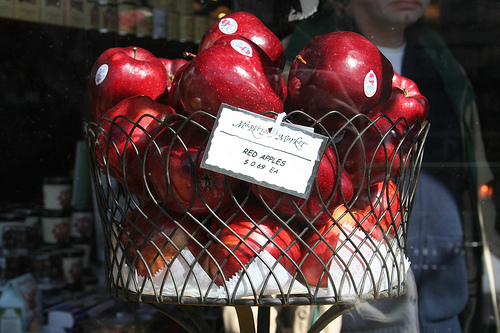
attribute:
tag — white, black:
[199, 101, 329, 201]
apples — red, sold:
[90, 11, 427, 286]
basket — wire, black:
[80, 112, 430, 306]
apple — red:
[285, 29, 395, 117]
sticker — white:
[362, 69, 378, 98]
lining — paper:
[104, 222, 410, 300]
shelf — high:
[0, 17, 202, 61]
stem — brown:
[294, 54, 313, 71]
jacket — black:
[282, 18, 470, 315]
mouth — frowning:
[388, 1, 423, 12]